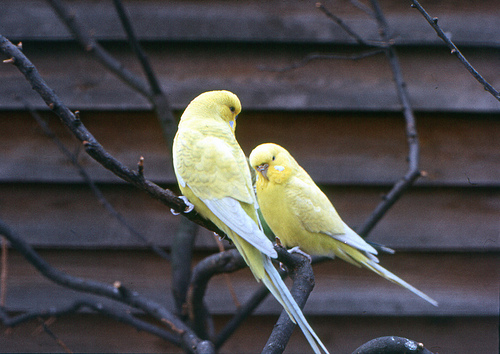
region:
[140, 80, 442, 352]
two yellow parakeets on a tree branch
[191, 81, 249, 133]
the head of a parakeet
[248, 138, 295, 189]
the head of a parakeet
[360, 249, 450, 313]
the tail feathers of a parakeet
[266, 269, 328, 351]
the tail feathers of a parakeet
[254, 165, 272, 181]
the beak of a parakeet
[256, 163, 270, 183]
the bill of a parakeet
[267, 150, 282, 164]
the eye of a parakeet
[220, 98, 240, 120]
the eye of a parakeet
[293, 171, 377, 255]
the wing of a parakeet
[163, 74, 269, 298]
Small yellow bird in a tree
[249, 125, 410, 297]
Small yellow bird in a tree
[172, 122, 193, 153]
Yellow feathers on a bird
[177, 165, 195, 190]
Yellow feathers on a bird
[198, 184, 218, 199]
Yellow feathers on a bird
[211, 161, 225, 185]
Yellow feathers on a bird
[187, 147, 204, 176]
Yellow feathers on a bird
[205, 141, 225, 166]
Yellow feathers on a bird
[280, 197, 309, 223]
Yellow feathers on a bird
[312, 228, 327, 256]
Yellow feathers on a bird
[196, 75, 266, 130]
head of a bird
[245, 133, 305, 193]
head of a bird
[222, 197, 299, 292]
tail of a bird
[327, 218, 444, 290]
tail of a bird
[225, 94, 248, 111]
eye of a bird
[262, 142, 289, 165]
eye of a bird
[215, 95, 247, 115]
an eye of a bird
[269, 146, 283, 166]
an eye of a bird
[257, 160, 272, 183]
peck of a bird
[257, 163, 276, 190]
a peck of a bird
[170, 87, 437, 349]
two yellow birds standing on branches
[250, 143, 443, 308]
a bird standing on a branch beside another bird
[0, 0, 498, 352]
two birds sitting on leafless branches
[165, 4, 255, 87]
part of a wooden siding on a building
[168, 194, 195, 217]
the foot of a yellow bird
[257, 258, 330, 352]
the tail of a yellow bird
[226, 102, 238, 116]
the yellow bird's eye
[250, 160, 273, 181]
a grey bill on a yellow bird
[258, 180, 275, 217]
the bird's yellow chest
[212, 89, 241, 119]
the yellow bird's head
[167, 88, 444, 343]
two yellow birds perched on branches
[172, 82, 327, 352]
yellow finch on a tree branch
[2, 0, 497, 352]
bare tree branch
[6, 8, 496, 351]
building in the background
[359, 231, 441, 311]
tail of the bird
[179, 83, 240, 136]
bird is looking to the right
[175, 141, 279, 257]
wing of the bird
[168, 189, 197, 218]
bird claw attached to a branch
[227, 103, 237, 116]
black eye on the right side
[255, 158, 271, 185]
gray beak on the bird